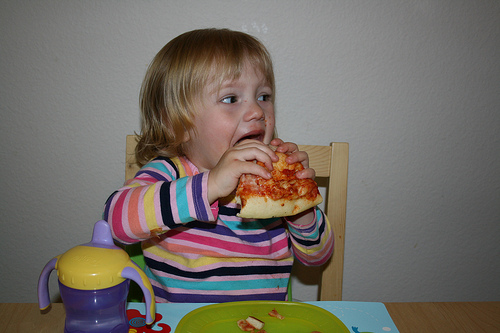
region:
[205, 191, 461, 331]
the table is wooden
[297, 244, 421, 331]
the table is wooden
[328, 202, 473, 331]
the table is wooden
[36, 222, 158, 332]
child's sipping cup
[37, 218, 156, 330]
lavender and yellow cup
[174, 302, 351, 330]
large, green plate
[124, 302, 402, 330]
blue place mat with red design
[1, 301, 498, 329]
tan, wooden table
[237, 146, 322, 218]
slice of pizza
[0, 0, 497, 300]
gray wall behind child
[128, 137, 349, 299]
Tan, wooden chair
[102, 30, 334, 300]
child eating a slice of pizza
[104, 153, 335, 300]
colorful, striped shirt being worn by child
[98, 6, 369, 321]
toddler eating a slice of pizza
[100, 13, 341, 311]
toddler wearing a colorful striped shirt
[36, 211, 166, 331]
purple and yellow toddler sippy cup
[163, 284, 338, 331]
green toddler plate with bits of food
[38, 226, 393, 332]
toddler cup with a placemat and plate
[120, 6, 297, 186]
toddler girl with blond hair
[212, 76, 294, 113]
toddler girl eyes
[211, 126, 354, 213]
two toddler hands holding a slice of pizza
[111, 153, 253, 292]
colorful striped toddler shirt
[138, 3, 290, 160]
face of a toddler eating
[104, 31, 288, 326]
The little girl is eating pizza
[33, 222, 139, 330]
A sippy cup is on the table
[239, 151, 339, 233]
The pizza is plain cheese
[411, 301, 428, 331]
The table is brown and wooden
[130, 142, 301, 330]
The shirt is striped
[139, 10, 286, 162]
The little girl has blonde hair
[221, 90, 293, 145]
Little girl has pizza on her face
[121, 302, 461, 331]
The place mat is designed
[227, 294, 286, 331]
There are pieces of food on the plate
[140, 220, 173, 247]
Pizza sauce on shirt sleeve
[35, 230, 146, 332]
purple and yellow kid's plastic cup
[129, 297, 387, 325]
blue placemat on wooden table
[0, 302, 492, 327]
wooden table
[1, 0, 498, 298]
white wall behind girl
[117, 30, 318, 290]
young girl eating slice of pizza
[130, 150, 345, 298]
wooden chair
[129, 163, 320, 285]
colorful striped shirt on girl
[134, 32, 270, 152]
girl has blonde hair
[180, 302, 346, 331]
green oval plate on placemat